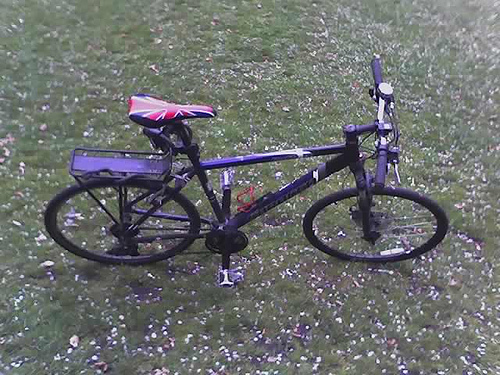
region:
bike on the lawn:
[20, 35, 456, 293]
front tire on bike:
[304, 183, 459, 275]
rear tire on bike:
[27, 175, 199, 271]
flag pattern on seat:
[128, 86, 203, 120]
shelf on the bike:
[68, 143, 171, 184]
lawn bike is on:
[8, 55, 476, 358]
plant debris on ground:
[258, 58, 348, 101]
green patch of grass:
[50, 297, 82, 321]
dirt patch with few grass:
[123, 278, 162, 304]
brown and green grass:
[147, 8, 307, 53]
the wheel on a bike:
[33, 186, 174, 297]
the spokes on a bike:
[86, 181, 176, 259]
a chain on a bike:
[108, 194, 265, 250]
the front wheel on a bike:
[294, 165, 448, 266]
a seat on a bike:
[127, 58, 225, 145]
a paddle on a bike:
[190, 260, 259, 314]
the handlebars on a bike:
[331, 47, 443, 222]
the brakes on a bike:
[376, 150, 421, 185]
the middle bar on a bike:
[189, 122, 345, 189]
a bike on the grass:
[79, 47, 444, 286]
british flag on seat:
[127, 90, 220, 122]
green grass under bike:
[0, 5, 499, 355]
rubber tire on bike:
[305, 186, 445, 266]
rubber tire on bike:
[39, 176, 194, 257]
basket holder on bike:
[60, 140, 162, 180]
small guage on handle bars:
[365, 79, 402, 107]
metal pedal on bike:
[212, 266, 245, 300]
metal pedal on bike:
[223, 165, 242, 187]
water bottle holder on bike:
[234, 190, 261, 211]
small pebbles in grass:
[58, 334, 103, 352]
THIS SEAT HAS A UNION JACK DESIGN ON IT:
[130, 95, 213, 125]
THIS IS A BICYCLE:
[25, 51, 450, 296]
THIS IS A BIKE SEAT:
[120, 80, 226, 120]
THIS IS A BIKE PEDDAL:
[206, 260, 249, 300]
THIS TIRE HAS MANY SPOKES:
[286, 183, 457, 272]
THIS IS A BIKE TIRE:
[288, 176, 453, 273]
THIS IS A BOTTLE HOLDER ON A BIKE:
[235, 177, 273, 226]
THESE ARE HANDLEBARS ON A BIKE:
[357, 52, 399, 199]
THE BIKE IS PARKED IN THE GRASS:
[33, 55, 464, 300]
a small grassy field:
[0, 0, 499, 373]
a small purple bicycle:
[39, 55, 449, 287]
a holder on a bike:
[63, 141, 178, 189]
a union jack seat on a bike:
[129, 89, 219, 129]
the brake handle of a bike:
[390, 144, 406, 186]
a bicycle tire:
[303, 183, 448, 268]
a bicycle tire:
[38, 178, 202, 270]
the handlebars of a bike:
[364, 60, 399, 194]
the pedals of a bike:
[213, 164, 253, 288]